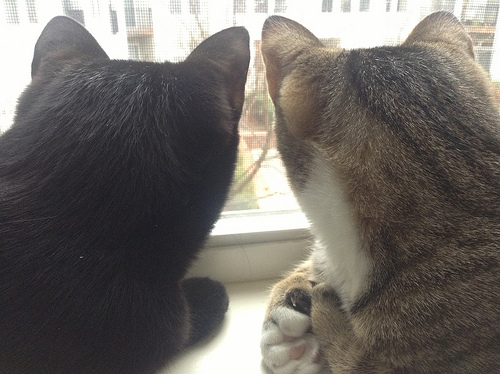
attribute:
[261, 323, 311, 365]
claw — sharp,  cat's,  poking out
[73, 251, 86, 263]
object — small, white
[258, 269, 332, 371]
paw — big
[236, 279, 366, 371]
paw — black 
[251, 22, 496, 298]
cat — light tan and white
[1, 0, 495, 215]
window —  large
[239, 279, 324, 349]
paw — big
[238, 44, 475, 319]
cat — light tan and white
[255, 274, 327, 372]
paw — big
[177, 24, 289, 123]
ear — black, cats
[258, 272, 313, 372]
paw — big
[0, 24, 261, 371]
cat — black ,   black, furry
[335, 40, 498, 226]
stripes — black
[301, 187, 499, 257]
neck — white 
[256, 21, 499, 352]
cat — light tan and white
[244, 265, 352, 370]
paw — big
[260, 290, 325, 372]
paw — big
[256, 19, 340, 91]
ear — cat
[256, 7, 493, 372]
cat — light tan and white, two colors, brown, striped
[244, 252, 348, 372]
paw — pink 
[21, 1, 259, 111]
ears — black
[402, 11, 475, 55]
ear — cat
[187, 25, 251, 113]
ear — cat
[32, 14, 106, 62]
ear — cat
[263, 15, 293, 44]
hair — long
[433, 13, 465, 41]
hair — long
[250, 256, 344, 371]
paw — big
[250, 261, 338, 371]
paw — big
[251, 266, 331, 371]
paw — big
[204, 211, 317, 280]
ledge —  white